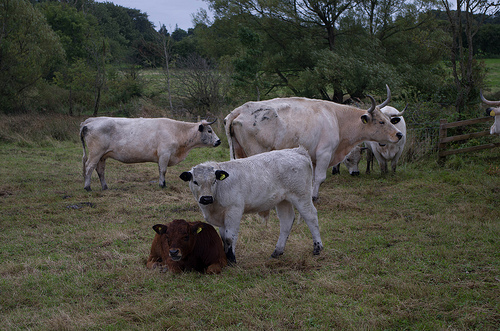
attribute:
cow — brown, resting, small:
[146, 219, 229, 274]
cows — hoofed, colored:
[77, 88, 415, 272]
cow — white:
[189, 148, 329, 261]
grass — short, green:
[9, 147, 496, 331]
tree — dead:
[144, 34, 225, 120]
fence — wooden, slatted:
[438, 119, 494, 160]